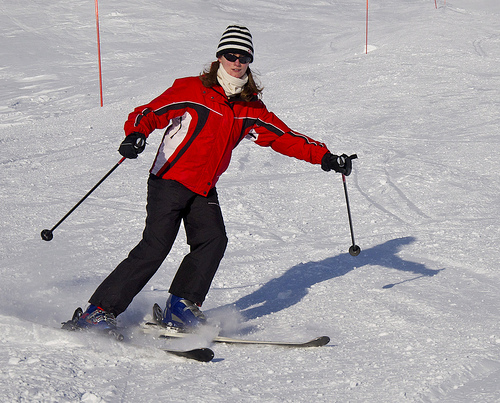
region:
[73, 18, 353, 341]
this is a lady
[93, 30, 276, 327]
the lady is snow surfing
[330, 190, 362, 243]
this is a stick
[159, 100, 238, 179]
this is the jacket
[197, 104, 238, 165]
the jacket is red in color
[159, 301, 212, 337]
she is wearing skiis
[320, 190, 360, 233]
the stick is thin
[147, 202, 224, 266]
the trousers are black in color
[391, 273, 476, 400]
the place is full of snow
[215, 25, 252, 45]
she is wearing marvin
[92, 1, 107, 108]
orange guide path poles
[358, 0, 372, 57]
orange guide path poles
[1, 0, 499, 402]
packed down fresh white snow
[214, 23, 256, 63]
black and white striped knit hat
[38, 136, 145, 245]
black and red ski pole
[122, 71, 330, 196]
red, black, and white ski jacket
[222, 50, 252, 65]
black framed sunglasses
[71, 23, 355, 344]
female snow skier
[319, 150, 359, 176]
black gloves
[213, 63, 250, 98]
white neck cowl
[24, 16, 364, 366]
one girl skiing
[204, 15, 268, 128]
girl with hat and sunglasses on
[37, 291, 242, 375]
kicking up snow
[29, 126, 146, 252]
ski stick up in air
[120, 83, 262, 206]
red polar jacket on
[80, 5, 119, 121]
path marker in snow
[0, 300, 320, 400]
ski shoes turned on snow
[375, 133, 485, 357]
snow ruffed up on hill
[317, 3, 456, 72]
ski path markers on trail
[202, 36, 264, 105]
long hair on girl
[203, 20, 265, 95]
Black and white striped hat on woman's head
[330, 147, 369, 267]
Ski pole being held by a hand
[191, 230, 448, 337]
Shadow of a skier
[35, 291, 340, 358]
A pair of skis and ski boots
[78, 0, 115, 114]
Pole to show the way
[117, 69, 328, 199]
Red, puffy ski jacket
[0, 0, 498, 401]
Ground covered in snow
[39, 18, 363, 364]
Woman skiing down a hill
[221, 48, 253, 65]
Sunglasses on a face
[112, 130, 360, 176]
Gloves to keep the hands warm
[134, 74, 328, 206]
jacket is red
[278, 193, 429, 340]
shadow is on the ground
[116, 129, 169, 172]
the gloves are black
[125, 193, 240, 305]
the pants are black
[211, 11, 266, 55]
the marvin is black and white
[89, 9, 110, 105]
the pole is red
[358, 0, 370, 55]
the pole is red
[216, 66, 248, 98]
the tshirt is white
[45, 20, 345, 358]
the person is a woman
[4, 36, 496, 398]
the surface is sloppy